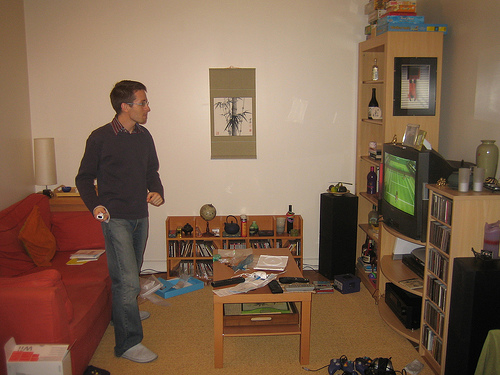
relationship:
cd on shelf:
[429, 226, 447, 240] [429, 172, 479, 366]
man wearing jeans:
[66, 79, 188, 374] [94, 210, 159, 355]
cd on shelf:
[426, 217, 452, 247] [414, 180, 466, 355]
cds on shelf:
[430, 192, 452, 227] [428, 213, 453, 230]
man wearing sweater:
[66, 79, 188, 374] [74, 117, 163, 220]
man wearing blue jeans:
[66, 79, 188, 374] [100, 222, 150, 345]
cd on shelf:
[442, 194, 450, 226] [425, 207, 455, 232]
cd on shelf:
[437, 224, 448, 252] [424, 235, 451, 260]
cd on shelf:
[437, 257, 451, 282] [421, 293, 449, 320]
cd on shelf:
[428, 305, 435, 327] [417, 317, 449, 347]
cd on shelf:
[424, 325, 432, 355] [357, 113, 387, 131]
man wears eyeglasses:
[66, 79, 188, 374] [104, 89, 178, 109]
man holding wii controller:
[66, 79, 188, 374] [88, 199, 110, 224]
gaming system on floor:
[333, 272, 361, 294] [89, 269, 435, 373]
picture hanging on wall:
[206, 80, 273, 159] [35, 12, 362, 215]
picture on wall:
[208, 65, 259, 161] [24, 0, 367, 271]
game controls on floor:
[312, 350, 405, 370] [114, 263, 427, 373]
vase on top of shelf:
[474, 134, 498, 190] [425, 179, 498, 199]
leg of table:
[212, 292, 224, 372] [206, 242, 316, 371]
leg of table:
[297, 298, 312, 367] [194, 246, 346, 368]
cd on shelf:
[427, 277, 445, 311] [421, 184, 451, 371]